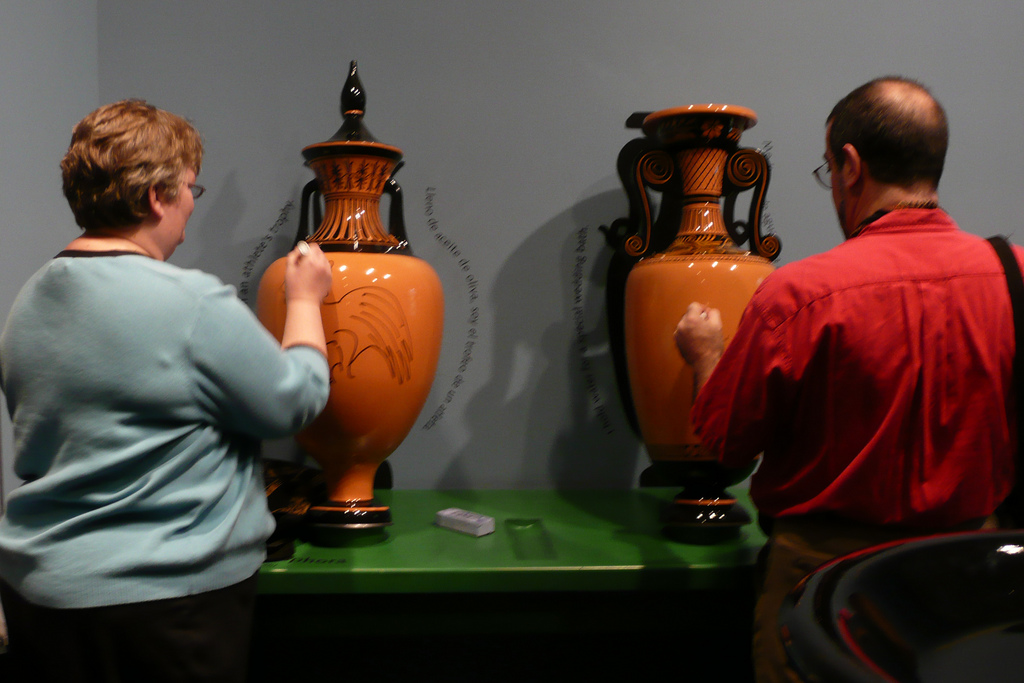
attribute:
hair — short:
[45, 83, 216, 244]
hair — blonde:
[60, 111, 164, 205]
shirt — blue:
[64, 258, 402, 563]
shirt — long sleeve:
[47, 296, 370, 577]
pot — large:
[244, 52, 452, 547]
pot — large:
[600, 89, 786, 541]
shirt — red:
[680, 201, 992, 552]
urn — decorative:
[244, 52, 452, 558]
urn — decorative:
[588, 78, 803, 552]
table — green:
[6, 478, 922, 679]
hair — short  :
[57, 94, 191, 237]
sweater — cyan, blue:
[0, 245, 342, 615]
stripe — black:
[309, 180, 348, 258]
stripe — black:
[322, 208, 348, 245]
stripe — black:
[333, 208, 359, 247]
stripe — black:
[322, 156, 355, 195]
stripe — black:
[350, 158, 377, 202]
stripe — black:
[320, 158, 355, 189]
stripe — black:
[350, 152, 381, 194]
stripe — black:
[359, 152, 375, 200]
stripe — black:
[359, 163, 392, 202]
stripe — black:
[339, 214, 361, 245]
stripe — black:
[326, 158, 348, 197]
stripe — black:
[333, 162, 360, 202]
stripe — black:
[343, 156, 372, 196]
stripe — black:
[311, 208, 344, 245]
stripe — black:
[337, 208, 361, 247]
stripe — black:
[320, 150, 344, 196]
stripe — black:
[344, 150, 375, 196]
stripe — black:
[365, 152, 389, 196]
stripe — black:
[331, 208, 349, 245]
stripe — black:
[348, 201, 377, 247]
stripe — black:
[315, 156, 359, 200]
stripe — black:
[348, 152, 375, 196]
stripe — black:
[359, 158, 381, 195]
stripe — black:
[337, 212, 366, 241]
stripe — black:
[309, 201, 349, 241]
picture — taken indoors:
[3, 3, 980, 663]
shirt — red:
[669, 204, 1022, 546]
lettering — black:
[409, 175, 489, 450]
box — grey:
[431, 497, 507, 545]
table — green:
[262, 476, 764, 569]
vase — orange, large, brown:
[236, 50, 450, 539]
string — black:
[861, 197, 952, 224]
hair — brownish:
[57, 96, 202, 233]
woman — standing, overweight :
[3, 83, 339, 673]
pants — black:
[22, 562, 258, 679]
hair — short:
[809, 72, 959, 207]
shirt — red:
[645, 188, 1021, 519]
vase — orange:
[252, 52, 449, 549]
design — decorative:
[318, 281, 420, 416]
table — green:
[269, 476, 807, 572]